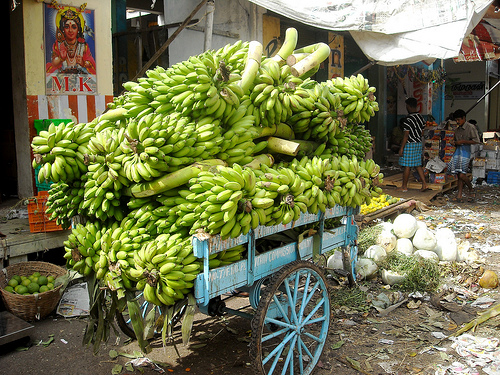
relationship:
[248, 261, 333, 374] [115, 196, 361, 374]
wheel on cart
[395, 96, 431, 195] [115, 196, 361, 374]
person near cart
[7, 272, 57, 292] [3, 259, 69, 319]
limes in basket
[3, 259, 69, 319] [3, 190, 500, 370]
basket on ground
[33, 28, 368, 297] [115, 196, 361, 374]
fruit in cart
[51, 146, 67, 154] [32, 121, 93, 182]
banana in bushel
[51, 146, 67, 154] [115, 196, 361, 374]
banana in cart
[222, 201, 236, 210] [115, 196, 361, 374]
banana in cart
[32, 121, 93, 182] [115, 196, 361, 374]
bushel in cart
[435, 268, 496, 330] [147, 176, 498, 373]
debris on street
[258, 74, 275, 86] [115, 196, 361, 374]
banana in cart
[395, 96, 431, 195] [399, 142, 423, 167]
person wearing skirt